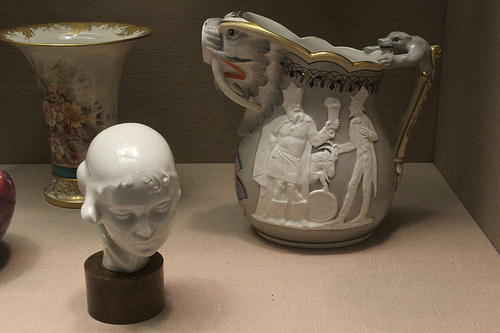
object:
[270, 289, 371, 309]
table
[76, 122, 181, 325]
bust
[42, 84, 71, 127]
flowers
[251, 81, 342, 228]
men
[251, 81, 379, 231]
design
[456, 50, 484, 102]
wall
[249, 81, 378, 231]
pitcher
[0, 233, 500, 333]
display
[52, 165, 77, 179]
band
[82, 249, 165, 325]
base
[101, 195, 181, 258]
face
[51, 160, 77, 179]
stripe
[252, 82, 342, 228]
man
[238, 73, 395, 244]
surface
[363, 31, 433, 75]
monster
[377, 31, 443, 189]
vase handle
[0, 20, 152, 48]
vase opening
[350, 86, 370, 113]
hat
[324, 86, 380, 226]
man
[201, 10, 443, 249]
vase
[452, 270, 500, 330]
table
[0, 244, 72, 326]
table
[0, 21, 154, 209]
vase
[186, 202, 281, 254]
shadow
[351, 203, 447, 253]
shadow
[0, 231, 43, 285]
shadow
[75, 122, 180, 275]
statue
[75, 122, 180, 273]
head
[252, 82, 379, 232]
two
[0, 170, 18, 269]
part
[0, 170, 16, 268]
vase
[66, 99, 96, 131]
old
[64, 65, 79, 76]
flower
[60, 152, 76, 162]
flower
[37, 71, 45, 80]
flower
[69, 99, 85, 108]
flower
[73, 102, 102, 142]
flowers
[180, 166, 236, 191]
table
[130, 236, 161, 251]
mouth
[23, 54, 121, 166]
paintings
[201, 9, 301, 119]
head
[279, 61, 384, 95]
decoration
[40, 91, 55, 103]
flower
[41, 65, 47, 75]
flower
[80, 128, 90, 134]
flower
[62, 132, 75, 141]
flower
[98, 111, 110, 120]
flower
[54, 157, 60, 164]
flower